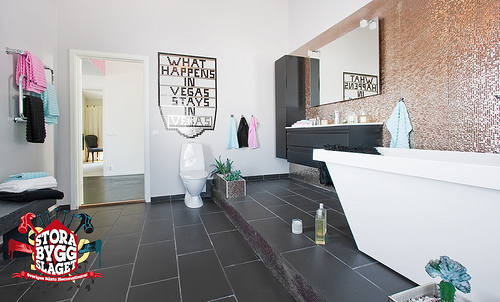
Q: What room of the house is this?
A: Bathroom.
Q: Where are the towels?
A: Towel rack.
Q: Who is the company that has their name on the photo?
A: Stora Bygg Slaget.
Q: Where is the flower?
A: Next to tub.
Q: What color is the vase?
A: Green.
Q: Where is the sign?
A: Above toilet.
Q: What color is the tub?
A: White.